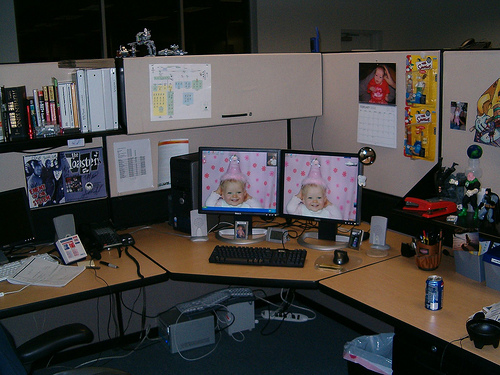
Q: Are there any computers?
A: Yes, there is a computer.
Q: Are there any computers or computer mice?
A: Yes, there is a computer.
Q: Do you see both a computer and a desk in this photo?
A: Yes, there are both a computer and a desk.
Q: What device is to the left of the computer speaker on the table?
A: The device is a computer.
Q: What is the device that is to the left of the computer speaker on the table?
A: The device is a computer.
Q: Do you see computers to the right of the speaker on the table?
A: No, the computer is to the left of the speaker.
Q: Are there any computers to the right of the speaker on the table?
A: No, the computer is to the left of the speaker.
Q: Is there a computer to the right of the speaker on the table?
A: No, the computer is to the left of the speaker.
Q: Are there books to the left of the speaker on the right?
A: No, there is a computer to the left of the speaker.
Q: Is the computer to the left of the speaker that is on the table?
A: Yes, the computer is to the left of the speaker.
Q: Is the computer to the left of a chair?
A: No, the computer is to the left of the speaker.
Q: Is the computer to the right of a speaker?
A: No, the computer is to the left of a speaker.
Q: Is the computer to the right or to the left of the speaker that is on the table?
A: The computer is to the left of the speaker.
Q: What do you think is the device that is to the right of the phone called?
A: The device is a computer.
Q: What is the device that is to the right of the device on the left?
A: The device is a computer.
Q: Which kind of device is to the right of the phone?
A: The device is a computer.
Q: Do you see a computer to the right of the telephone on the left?
A: Yes, there is a computer to the right of the phone.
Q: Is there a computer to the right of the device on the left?
A: Yes, there is a computer to the right of the phone.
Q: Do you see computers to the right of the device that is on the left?
A: Yes, there is a computer to the right of the phone.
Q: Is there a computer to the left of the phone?
A: No, the computer is to the right of the phone.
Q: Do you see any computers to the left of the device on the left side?
A: No, the computer is to the right of the phone.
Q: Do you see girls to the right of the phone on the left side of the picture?
A: No, there is a computer to the right of the phone.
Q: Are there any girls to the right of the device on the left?
A: No, there is a computer to the right of the phone.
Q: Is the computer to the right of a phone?
A: Yes, the computer is to the right of a phone.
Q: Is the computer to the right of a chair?
A: No, the computer is to the right of a phone.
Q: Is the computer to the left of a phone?
A: No, the computer is to the right of a phone.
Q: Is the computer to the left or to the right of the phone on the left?
A: The computer is to the right of the telephone.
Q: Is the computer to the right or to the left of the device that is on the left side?
A: The computer is to the right of the telephone.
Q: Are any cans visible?
A: Yes, there is a can.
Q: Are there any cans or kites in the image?
A: Yes, there is a can.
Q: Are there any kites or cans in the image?
A: Yes, there is a can.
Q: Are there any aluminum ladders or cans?
A: Yes, there is an aluminum can.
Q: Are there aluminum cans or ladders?
A: Yes, there is an aluminum can.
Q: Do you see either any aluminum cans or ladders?
A: Yes, there is an aluminum can.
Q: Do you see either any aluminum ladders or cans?
A: Yes, there is an aluminum can.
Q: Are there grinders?
A: No, there are no grinders.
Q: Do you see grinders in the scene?
A: No, there are no grinders.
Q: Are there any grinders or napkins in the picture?
A: No, there are no grinders or napkins.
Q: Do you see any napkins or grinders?
A: No, there are no grinders or napkins.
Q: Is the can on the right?
A: Yes, the can is on the right of the image.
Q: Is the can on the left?
A: No, the can is on the right of the image.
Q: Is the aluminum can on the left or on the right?
A: The can is on the right of the image.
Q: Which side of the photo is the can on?
A: The can is on the right of the image.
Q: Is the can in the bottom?
A: Yes, the can is in the bottom of the image.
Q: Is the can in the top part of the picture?
A: No, the can is in the bottom of the image.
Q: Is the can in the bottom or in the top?
A: The can is in the bottom of the image.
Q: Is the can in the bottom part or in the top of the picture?
A: The can is in the bottom of the image.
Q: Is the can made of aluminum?
A: Yes, the can is made of aluminum.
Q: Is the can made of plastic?
A: No, the can is made of aluminum.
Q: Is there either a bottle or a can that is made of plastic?
A: No, there is a can but it is made of aluminum.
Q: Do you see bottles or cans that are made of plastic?
A: No, there is a can but it is made of aluminum.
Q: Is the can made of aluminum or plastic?
A: The can is made of aluminum.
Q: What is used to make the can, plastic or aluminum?
A: The can is made of aluminum.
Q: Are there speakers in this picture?
A: Yes, there are speakers.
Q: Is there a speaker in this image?
A: Yes, there are speakers.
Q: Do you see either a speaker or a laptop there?
A: Yes, there are speakers.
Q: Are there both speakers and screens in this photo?
A: Yes, there are both speakers and a screen.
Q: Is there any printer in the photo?
A: No, there are no printers.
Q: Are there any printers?
A: No, there are no printers.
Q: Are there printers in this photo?
A: No, there are no printers.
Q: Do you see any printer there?
A: No, there are no printers.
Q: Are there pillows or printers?
A: No, there are no printers or pillows.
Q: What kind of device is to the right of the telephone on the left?
A: The devices are speakers.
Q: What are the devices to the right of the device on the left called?
A: The devices are speakers.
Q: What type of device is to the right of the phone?
A: The devices are speakers.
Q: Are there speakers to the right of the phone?
A: Yes, there are speakers to the right of the phone.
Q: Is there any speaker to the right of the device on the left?
A: Yes, there are speakers to the right of the phone.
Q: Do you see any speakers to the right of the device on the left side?
A: Yes, there are speakers to the right of the phone.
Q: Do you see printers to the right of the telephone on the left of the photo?
A: No, there are speakers to the right of the phone.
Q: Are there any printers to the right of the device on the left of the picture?
A: No, there are speakers to the right of the phone.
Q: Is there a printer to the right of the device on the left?
A: No, there are speakers to the right of the phone.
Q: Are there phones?
A: Yes, there is a phone.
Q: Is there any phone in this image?
A: Yes, there is a phone.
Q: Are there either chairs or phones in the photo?
A: Yes, there is a phone.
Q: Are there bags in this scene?
A: No, there are no bags.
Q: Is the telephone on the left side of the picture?
A: Yes, the telephone is on the left of the image.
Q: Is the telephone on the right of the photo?
A: No, the telephone is on the left of the image.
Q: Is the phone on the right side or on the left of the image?
A: The phone is on the left of the image.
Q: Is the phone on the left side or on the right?
A: The phone is on the left of the image.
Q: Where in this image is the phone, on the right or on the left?
A: The phone is on the left of the image.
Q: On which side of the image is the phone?
A: The phone is on the left of the image.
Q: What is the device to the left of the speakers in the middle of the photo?
A: The device is a phone.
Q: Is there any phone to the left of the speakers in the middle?
A: Yes, there is a phone to the left of the speakers.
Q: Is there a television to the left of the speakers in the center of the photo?
A: No, there is a phone to the left of the speakers.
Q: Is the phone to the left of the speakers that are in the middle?
A: Yes, the phone is to the left of the speakers.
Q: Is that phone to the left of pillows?
A: No, the phone is to the left of the speakers.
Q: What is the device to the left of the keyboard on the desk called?
A: The device is a phone.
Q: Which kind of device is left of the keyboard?
A: The device is a phone.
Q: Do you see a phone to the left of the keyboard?
A: Yes, there is a phone to the left of the keyboard.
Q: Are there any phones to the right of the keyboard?
A: No, the phone is to the left of the keyboard.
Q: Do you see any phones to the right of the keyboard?
A: No, the phone is to the left of the keyboard.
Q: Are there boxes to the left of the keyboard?
A: No, there is a phone to the left of the keyboard.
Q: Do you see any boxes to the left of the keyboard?
A: No, there is a phone to the left of the keyboard.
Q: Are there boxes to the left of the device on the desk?
A: No, there is a phone to the left of the keyboard.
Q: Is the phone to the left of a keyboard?
A: Yes, the phone is to the left of a keyboard.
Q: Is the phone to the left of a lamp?
A: No, the phone is to the left of a keyboard.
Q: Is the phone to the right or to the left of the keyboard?
A: The phone is to the left of the keyboard.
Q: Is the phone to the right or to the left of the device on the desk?
A: The phone is to the left of the keyboard.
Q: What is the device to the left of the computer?
A: The device is a phone.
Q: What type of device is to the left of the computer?
A: The device is a phone.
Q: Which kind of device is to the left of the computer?
A: The device is a phone.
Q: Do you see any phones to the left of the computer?
A: Yes, there is a phone to the left of the computer.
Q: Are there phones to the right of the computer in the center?
A: No, the phone is to the left of the computer.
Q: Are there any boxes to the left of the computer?
A: No, there is a phone to the left of the computer.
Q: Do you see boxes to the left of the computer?
A: No, there is a phone to the left of the computer.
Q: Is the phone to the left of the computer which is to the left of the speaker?
A: Yes, the phone is to the left of the computer.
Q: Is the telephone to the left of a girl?
A: No, the telephone is to the left of the computer.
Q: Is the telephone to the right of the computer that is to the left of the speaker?
A: No, the telephone is to the left of the computer.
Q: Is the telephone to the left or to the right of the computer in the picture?
A: The telephone is to the left of the computer.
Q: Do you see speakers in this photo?
A: Yes, there is a speaker.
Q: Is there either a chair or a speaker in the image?
A: Yes, there is a speaker.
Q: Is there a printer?
A: No, there are no printers.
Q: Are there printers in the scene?
A: No, there are no printers.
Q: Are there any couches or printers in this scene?
A: No, there are no printers or couches.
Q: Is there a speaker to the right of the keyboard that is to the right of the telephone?
A: Yes, there is a speaker to the right of the keyboard.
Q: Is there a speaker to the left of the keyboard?
A: No, the speaker is to the right of the keyboard.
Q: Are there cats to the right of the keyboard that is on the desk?
A: No, there is a speaker to the right of the keyboard.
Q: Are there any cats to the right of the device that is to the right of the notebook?
A: No, there is a speaker to the right of the keyboard.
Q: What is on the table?
A: The speaker is on the table.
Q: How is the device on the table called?
A: The device is a speaker.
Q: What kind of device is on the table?
A: The device is a speaker.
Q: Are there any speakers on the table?
A: Yes, there is a speaker on the table.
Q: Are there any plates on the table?
A: No, there is a speaker on the table.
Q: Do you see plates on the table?
A: No, there is a speaker on the table.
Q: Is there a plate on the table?
A: No, there is a speaker on the table.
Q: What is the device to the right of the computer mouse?
A: The device is a speaker.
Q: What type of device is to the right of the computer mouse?
A: The device is a speaker.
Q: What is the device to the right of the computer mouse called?
A: The device is a speaker.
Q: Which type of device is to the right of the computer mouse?
A: The device is a speaker.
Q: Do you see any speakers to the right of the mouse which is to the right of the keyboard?
A: Yes, there is a speaker to the right of the mouse.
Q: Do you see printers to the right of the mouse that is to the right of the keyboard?
A: No, there is a speaker to the right of the computer mouse.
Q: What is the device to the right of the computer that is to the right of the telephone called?
A: The device is a speaker.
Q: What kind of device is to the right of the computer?
A: The device is a speaker.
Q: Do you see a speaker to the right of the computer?
A: Yes, there is a speaker to the right of the computer.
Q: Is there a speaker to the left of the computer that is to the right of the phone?
A: No, the speaker is to the right of the computer.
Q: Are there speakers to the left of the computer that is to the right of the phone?
A: No, the speaker is to the right of the computer.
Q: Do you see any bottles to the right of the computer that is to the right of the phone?
A: No, there is a speaker to the right of the computer.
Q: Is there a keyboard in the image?
A: Yes, there is a keyboard.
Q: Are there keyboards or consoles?
A: Yes, there is a keyboard.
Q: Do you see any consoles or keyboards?
A: Yes, there is a keyboard.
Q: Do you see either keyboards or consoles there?
A: Yes, there is a keyboard.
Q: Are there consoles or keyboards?
A: Yes, there is a keyboard.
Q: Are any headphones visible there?
A: No, there are no headphones.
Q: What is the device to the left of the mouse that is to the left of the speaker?
A: The device is a keyboard.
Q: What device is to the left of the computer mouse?
A: The device is a keyboard.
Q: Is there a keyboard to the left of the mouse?
A: Yes, there is a keyboard to the left of the mouse.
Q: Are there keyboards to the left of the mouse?
A: Yes, there is a keyboard to the left of the mouse.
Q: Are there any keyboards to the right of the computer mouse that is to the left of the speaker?
A: No, the keyboard is to the left of the computer mouse.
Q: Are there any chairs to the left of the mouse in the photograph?
A: No, there is a keyboard to the left of the mouse.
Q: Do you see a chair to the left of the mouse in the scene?
A: No, there is a keyboard to the left of the mouse.